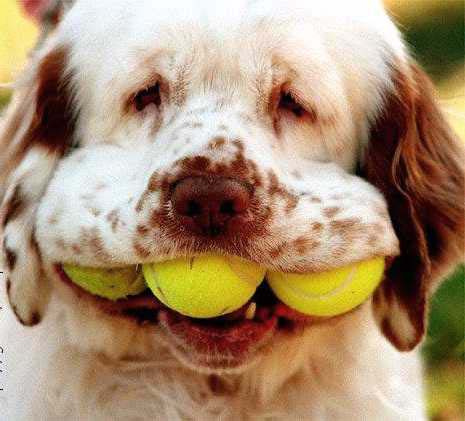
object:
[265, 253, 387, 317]
balls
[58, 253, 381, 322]
muzzle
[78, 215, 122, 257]
spots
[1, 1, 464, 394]
head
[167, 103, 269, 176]
yes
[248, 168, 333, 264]
yes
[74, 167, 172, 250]
yes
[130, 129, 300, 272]
yes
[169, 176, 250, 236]
nose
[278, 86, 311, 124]
eyes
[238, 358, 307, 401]
fur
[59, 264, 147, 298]
balls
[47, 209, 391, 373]
mouth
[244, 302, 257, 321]
tooth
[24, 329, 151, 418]
fur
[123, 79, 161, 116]
eyes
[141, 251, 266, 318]
ball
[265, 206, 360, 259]
brown spots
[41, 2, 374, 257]
dog's face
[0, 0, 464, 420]
dog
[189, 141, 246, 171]
spots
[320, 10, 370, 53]
fur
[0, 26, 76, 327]
ear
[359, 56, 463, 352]
ear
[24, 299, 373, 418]
neck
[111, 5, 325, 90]
forehead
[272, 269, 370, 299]
seam